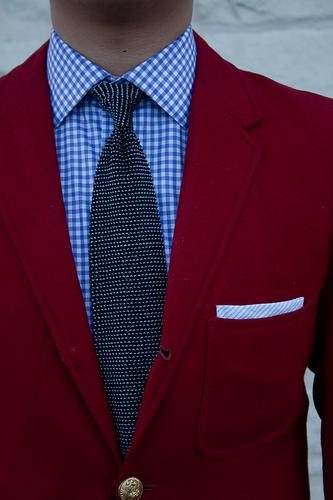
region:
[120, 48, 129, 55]
beauty mark on the neck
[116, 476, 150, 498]
button on the jacket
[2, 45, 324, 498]
the jacket is red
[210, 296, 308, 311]
the hankerchief in the pocket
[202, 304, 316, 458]
the pocket on the jacket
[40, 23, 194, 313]
the shirt is checkered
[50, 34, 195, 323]
the shirt is blue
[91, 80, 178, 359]
the tie is blue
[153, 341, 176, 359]
the button hole on the jacket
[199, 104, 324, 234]
this is a suit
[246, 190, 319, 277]
the suit is red in color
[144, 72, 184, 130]
the shirt is blue and white in color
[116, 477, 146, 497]
this is a button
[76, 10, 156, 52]
this is the neck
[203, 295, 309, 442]
this is the pocket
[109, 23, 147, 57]
the man is light skinned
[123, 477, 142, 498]
the button is big in size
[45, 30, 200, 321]
blue and white checked shirt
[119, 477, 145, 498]
silver button on the jacket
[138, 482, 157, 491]
small slit in the jacket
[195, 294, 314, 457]
pocket on the chest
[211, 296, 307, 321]
blue and white stripes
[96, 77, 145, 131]
knot at the top of the tie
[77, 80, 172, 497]
tie hanging down the torso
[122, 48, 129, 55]
small brown freckle on the neck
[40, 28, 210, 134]
collar of the shirt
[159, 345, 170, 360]
hole for the button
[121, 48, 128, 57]
this is a birth mark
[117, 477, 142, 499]
this is a button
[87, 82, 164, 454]
this is a tie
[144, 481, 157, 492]
ths is a button hole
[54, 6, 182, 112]
this is a kneck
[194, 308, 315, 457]
this is a pocket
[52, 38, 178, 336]
this is a shirt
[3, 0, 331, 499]
this is a person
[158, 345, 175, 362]
this is a button hole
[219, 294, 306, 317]
this is an handkerchief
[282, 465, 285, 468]
partr of a coat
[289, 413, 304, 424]
part of an arm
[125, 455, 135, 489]
part of a button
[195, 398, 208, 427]
edge of a coat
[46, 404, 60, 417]
edge of a coat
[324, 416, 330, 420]
part of a finger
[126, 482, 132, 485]
part of a button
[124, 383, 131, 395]
edge of a tie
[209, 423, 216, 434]
part of a shirt